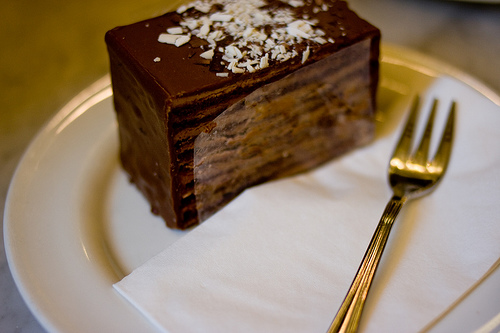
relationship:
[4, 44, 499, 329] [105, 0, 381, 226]
plate with cake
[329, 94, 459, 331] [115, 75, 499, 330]
fork on napkin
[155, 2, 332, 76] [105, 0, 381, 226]
sprinkles on top of cake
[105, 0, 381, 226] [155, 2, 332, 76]
cake with sprinkles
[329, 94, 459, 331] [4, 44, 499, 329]
fork on plate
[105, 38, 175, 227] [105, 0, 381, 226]
chocolate coating on side of cake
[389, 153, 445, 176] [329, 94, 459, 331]
light reflected on fork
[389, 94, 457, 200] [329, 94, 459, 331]
tines on fork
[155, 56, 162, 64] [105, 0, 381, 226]
sprinkle on top of cake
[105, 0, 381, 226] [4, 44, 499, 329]
cake on plate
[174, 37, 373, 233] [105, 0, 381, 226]
layers in cake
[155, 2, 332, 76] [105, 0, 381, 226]
sprinkles atop cake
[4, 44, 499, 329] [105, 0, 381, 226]
plate with a piece of cake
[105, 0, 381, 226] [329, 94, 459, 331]
cake next to fork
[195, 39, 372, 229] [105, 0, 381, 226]
paper on cake